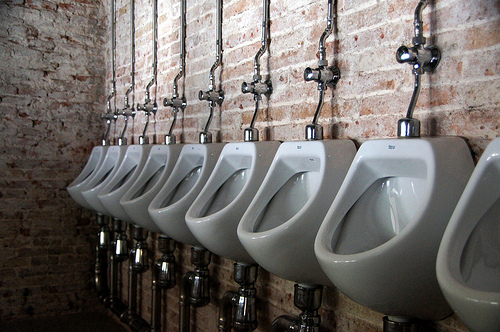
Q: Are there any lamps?
A: No, there are no lamps.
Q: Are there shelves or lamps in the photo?
A: No, there are no lamps or shelves.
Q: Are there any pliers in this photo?
A: No, there are no pliers.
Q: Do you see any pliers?
A: No, there are no pliers.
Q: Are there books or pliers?
A: No, there are no pliers or books.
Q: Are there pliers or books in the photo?
A: No, there are no pliers or books.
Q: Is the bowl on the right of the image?
A: Yes, the bowl is on the right of the image.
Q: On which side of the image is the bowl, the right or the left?
A: The bowl is on the right of the image.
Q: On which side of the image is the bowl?
A: The bowl is on the right of the image.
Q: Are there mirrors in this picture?
A: No, there are no mirrors.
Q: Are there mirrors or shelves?
A: No, there are no mirrors or shelves.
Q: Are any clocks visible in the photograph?
A: No, there are no clocks.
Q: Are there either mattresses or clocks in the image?
A: No, there are no clocks or mattresses.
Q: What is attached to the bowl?
A: The pipe is attached to the bowl.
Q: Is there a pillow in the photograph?
A: No, there are no pillows.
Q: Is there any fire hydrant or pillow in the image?
A: No, there are no pillows or fire hydrants.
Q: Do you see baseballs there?
A: No, there are no baseballs.